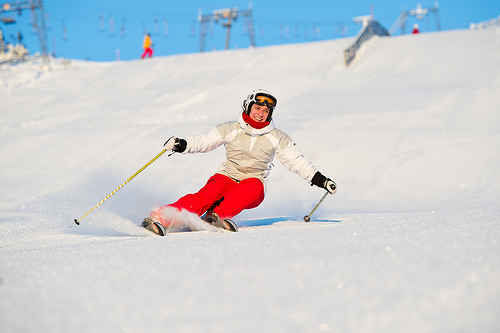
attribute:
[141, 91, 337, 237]
woman — skiing, smiling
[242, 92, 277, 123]
helmet — white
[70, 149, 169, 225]
ski pole — yellow, white, black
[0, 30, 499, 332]
snow — white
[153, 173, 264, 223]
pants — red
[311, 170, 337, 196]
glove — black, white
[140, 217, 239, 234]
skis — pair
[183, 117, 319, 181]
jacket — white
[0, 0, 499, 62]
sky — blue